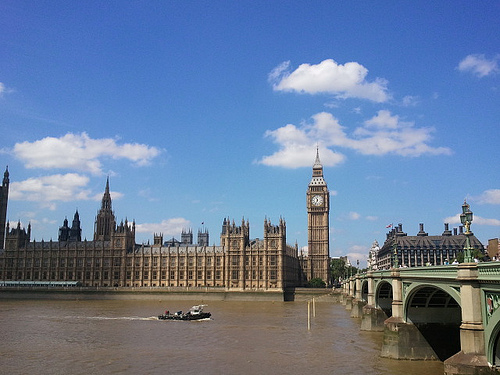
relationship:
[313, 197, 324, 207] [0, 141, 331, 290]
clock on building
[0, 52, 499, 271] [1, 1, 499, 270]
cloud in sky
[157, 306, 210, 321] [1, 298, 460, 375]
boat in river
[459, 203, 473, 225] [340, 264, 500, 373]
lights are on bridge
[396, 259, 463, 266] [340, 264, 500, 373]
people are on bridge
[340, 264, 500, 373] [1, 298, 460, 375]
bridge over river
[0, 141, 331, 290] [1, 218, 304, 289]
building beside building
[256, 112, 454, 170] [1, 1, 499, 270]
cloud in sky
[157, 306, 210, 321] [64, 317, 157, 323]
boat creating waves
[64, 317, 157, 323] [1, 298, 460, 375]
waves are in river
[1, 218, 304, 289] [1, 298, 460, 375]
building by river